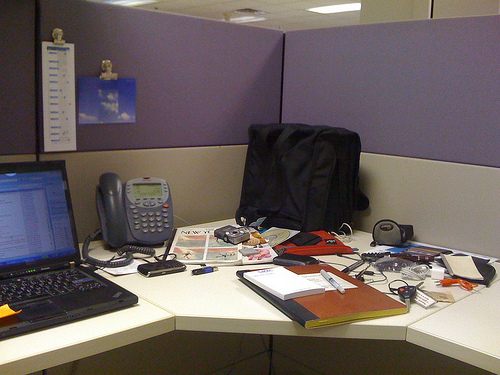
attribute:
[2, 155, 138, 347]
laptop — open, black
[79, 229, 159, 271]
cord — gray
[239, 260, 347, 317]
notepad — white, spiral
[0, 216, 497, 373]
desk — white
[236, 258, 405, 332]
book — brown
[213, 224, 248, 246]
camera — small, silver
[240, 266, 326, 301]
notepad — white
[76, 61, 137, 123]
paper — hanging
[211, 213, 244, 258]
camera — silver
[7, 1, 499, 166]
wall — light purple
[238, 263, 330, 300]
notepad — white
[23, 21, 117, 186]
paper — hanging